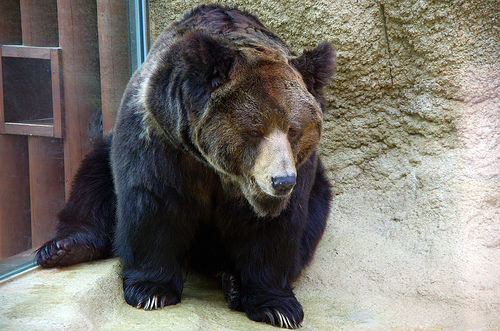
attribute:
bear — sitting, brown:
[36, 10, 364, 325]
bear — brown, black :
[108, 15, 359, 290]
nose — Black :
[266, 174, 301, 196]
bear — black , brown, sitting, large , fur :
[34, 4, 332, 328]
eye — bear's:
[238, 122, 263, 146]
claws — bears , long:
[131, 276, 184, 328]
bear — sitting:
[136, 39, 341, 270]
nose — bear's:
[271, 175, 298, 192]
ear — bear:
[181, 23, 255, 90]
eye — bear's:
[287, 119, 308, 141]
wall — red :
[1, 3, 132, 263]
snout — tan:
[256, 137, 302, 193]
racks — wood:
[4, 6, 173, 231]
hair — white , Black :
[117, 133, 187, 288]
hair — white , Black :
[243, 212, 304, 312]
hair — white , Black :
[70, 131, 119, 235]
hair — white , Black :
[240, 45, 306, 124]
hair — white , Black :
[151, 8, 196, 63]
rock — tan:
[117, 28, 349, 320]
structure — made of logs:
[9, 9, 100, 139]